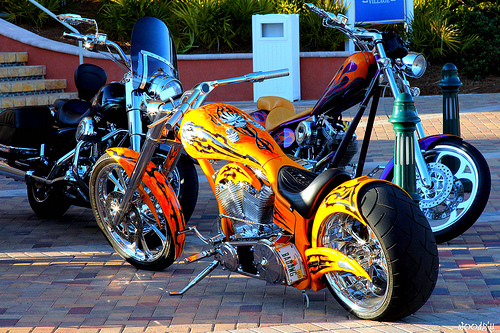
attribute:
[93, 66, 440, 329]
motorcycle — flame painted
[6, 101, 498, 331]
pavement — brick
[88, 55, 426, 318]
motorcycle — orange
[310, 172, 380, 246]
fender — yellow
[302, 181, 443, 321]
tire — large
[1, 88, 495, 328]
ground — brick pavers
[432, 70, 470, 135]
pole — green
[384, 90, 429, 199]
pole — green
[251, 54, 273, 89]
post box — white